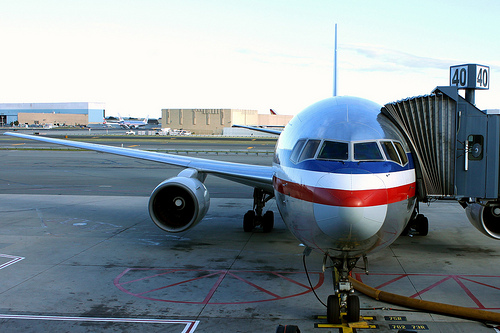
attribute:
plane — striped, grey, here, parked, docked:
[2, 20, 429, 324]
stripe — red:
[270, 174, 418, 208]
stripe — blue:
[269, 148, 417, 175]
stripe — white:
[271, 162, 417, 192]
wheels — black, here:
[325, 294, 361, 324]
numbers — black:
[451, 68, 488, 87]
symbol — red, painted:
[113, 265, 326, 305]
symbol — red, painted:
[356, 271, 500, 312]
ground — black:
[1, 160, 500, 331]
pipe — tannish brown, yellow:
[343, 271, 500, 325]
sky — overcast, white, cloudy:
[3, 0, 499, 118]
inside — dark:
[289, 139, 409, 166]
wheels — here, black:
[242, 209, 277, 234]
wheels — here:
[401, 211, 429, 237]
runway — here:
[3, 135, 282, 163]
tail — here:
[231, 23, 339, 137]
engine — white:
[146, 168, 213, 235]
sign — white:
[449, 64, 491, 90]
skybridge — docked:
[375, 85, 500, 201]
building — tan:
[159, 107, 295, 133]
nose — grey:
[283, 195, 411, 255]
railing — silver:
[140, 147, 276, 157]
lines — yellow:
[308, 263, 376, 332]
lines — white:
[2, 252, 201, 332]